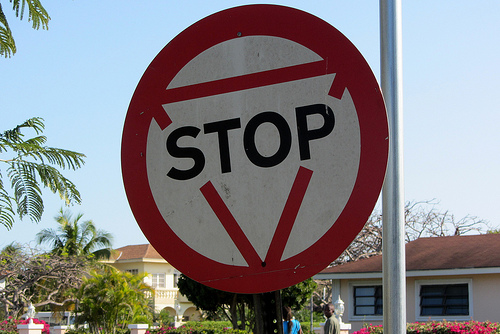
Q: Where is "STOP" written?
A: On round sign.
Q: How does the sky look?
A: Blue and clear.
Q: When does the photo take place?
A: During daytime.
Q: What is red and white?
A: A stop sign.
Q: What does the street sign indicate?
A: Stop.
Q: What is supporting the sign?
A: A pole.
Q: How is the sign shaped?
A: Like a circle.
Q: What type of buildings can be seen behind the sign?
A: Houses.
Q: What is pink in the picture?
A: Flowers.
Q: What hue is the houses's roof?
A: Red.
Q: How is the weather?
A: Clear and sunny.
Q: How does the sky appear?
A: White and blue and cloudless.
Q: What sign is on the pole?
A: Stop sign.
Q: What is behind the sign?
A: A house.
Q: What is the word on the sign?
A: Stop.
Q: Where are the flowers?
A: In the bush.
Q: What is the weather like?
A: Sunny.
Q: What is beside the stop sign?
A: A pole.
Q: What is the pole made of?
A: Metal.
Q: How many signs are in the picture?
A: One.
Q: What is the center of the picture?
A: A sign.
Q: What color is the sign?
A: Red, black and white.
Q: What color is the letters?
A: Black.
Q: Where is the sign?
A: On a pole.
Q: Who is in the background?
A: Two people.